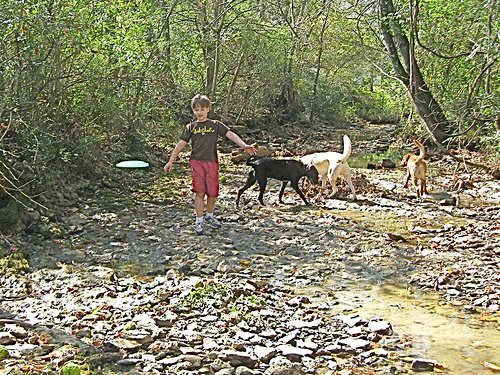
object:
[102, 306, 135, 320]
rocks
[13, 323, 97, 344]
ground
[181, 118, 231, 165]
helmet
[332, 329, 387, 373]
ground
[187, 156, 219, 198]
pants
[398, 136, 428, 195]
dog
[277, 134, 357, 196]
dog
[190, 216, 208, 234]
tennis shoes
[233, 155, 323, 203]
black dog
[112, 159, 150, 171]
frisbee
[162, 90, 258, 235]
boy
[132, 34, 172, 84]
forest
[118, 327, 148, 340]
stones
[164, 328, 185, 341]
stones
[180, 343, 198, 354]
stones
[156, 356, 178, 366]
stones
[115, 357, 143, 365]
stones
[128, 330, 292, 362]
ground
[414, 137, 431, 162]
tail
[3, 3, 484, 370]
woods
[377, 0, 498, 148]
trees